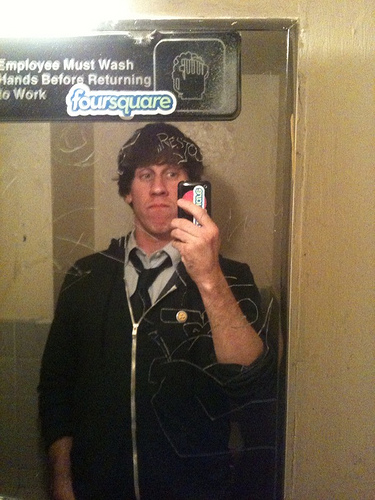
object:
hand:
[170, 197, 222, 281]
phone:
[178, 180, 211, 227]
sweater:
[37, 229, 268, 500]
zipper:
[115, 253, 179, 500]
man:
[36, 120, 278, 500]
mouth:
[147, 202, 170, 209]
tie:
[129, 248, 170, 323]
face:
[130, 162, 191, 234]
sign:
[0, 34, 242, 123]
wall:
[3, 0, 375, 497]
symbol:
[152, 37, 226, 106]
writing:
[16, 98, 295, 471]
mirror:
[0, 20, 295, 500]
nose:
[149, 173, 168, 197]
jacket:
[36, 229, 265, 500]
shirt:
[123, 228, 182, 326]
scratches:
[0, 127, 293, 440]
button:
[176, 310, 188, 323]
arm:
[169, 197, 278, 390]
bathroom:
[0, 0, 374, 498]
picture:
[0, 0, 374, 500]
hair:
[117, 121, 204, 198]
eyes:
[141, 173, 152, 179]